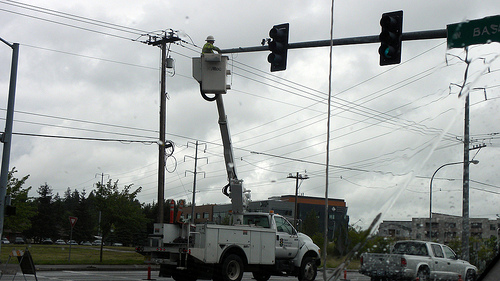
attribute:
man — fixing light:
[201, 32, 224, 58]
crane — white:
[204, 74, 246, 224]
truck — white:
[156, 197, 317, 280]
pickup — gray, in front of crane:
[356, 224, 487, 280]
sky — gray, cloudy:
[205, 16, 257, 36]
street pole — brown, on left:
[151, 54, 177, 197]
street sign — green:
[440, 4, 494, 63]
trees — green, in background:
[45, 197, 145, 243]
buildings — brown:
[285, 191, 350, 275]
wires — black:
[9, 1, 150, 57]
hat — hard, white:
[203, 37, 219, 43]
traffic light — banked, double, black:
[375, 4, 405, 76]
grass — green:
[47, 251, 67, 261]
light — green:
[378, 49, 395, 57]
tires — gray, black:
[280, 251, 332, 279]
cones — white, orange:
[145, 257, 158, 280]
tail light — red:
[396, 257, 406, 265]